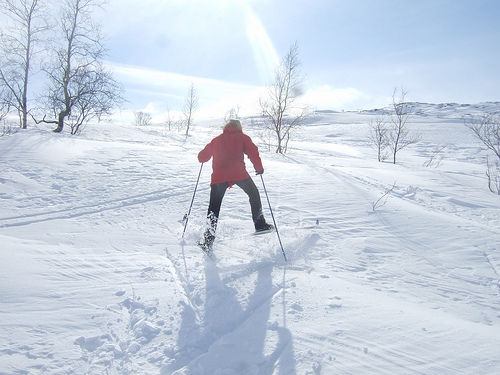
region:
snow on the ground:
[12, 83, 499, 371]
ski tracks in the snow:
[115, 209, 326, 374]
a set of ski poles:
[156, 136, 297, 256]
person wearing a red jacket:
[180, 123, 276, 188]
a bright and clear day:
[3, 3, 493, 345]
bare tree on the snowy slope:
[387, 84, 416, 168]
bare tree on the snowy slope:
[367, 114, 388, 170]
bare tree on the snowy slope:
[264, 40, 301, 158]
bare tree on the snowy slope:
[178, 79, 201, 138]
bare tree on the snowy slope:
[51, 2, 98, 130]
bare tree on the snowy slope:
[67, 61, 96, 143]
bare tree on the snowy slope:
[2, 0, 45, 129]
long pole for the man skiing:
[175, 160, 204, 235]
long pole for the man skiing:
[255, 172, 294, 273]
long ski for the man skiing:
[206, 216, 321, 248]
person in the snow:
[194, 116, 276, 256]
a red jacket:
[198, 122, 263, 190]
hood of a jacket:
[219, 124, 240, 133]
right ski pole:
[254, 165, 294, 267]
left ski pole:
[179, 158, 207, 240]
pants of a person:
[197, 175, 273, 248]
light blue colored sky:
[1, 0, 498, 134]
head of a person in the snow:
[223, 116, 249, 137]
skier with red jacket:
[184, 109, 281, 240]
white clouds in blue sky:
[337, 9, 388, 47]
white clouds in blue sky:
[424, 26, 496, 71]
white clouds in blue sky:
[341, 42, 375, 74]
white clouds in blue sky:
[352, 19, 412, 60]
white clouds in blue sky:
[234, 8, 299, 39]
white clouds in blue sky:
[202, 48, 230, 82]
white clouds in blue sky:
[217, 16, 278, 61]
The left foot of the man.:
[198, 184, 223, 241]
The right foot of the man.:
[234, 181, 268, 224]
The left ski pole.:
[179, 160, 211, 244]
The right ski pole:
[255, 175, 302, 256]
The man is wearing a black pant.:
[195, 180, 265, 230]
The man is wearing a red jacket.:
[190, 132, 265, 175]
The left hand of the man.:
[188, 132, 220, 162]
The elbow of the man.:
[193, 148, 210, 163]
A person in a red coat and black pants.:
[197, 119, 274, 251]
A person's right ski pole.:
[257, 172, 287, 262]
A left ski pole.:
[180, 159, 202, 238]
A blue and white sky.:
[0, 2, 498, 120]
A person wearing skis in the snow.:
[200, 210, 288, 252]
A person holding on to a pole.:
[181, 158, 206, 233]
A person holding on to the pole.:
[252, 163, 290, 270]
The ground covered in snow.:
[8, 114, 496, 372]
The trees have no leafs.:
[368, 95, 419, 162]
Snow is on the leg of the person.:
[185, 209, 224, 256]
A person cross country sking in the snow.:
[176, 114, 289, 254]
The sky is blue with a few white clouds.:
[13, 5, 493, 109]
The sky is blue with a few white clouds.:
[2, 0, 499, 112]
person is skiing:
[173, 112, 287, 252]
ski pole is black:
[170, 152, 205, 251]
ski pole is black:
[260, 173, 293, 278]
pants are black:
[200, 182, 271, 240]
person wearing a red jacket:
[177, 123, 265, 190]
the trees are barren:
[358, 88, 418, 173]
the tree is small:
[370, 123, 388, 166]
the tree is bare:
[236, 22, 311, 159]